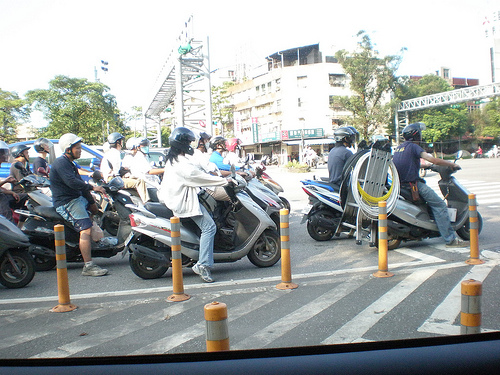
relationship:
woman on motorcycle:
[149, 136, 209, 258] [134, 174, 295, 280]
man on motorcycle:
[395, 120, 456, 242] [134, 174, 295, 280]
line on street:
[272, 282, 359, 330] [235, 179, 477, 285]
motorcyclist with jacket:
[312, 113, 371, 238] [164, 161, 226, 234]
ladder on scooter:
[353, 146, 401, 229] [33, 193, 156, 267]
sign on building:
[277, 114, 343, 154] [224, 69, 384, 169]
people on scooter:
[47, 117, 431, 206] [33, 193, 156, 267]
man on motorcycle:
[395, 120, 456, 242] [312, 128, 482, 249]